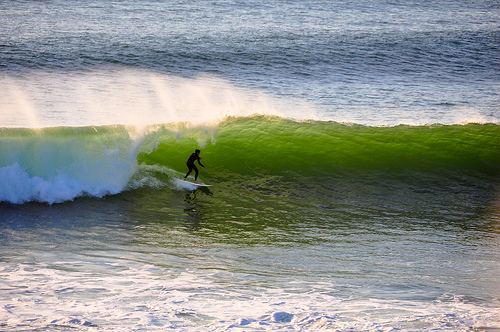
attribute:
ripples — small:
[18, 284, 78, 316]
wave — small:
[329, 26, 399, 116]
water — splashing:
[261, 12, 450, 108]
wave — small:
[1, 110, 494, 214]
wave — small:
[387, 301, 442, 326]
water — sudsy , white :
[337, 136, 437, 273]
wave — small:
[46, 55, 188, 225]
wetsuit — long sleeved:
[168, 148, 213, 189]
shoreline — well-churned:
[6, 311, 491, 330]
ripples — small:
[12, 262, 497, 329]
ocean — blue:
[6, 8, 498, 114]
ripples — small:
[93, 291, 313, 329]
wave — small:
[0, 27, 499, 80]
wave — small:
[0, 116, 481, 202]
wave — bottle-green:
[126, 119, 479, 206]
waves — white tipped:
[0, 217, 482, 329]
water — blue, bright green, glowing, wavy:
[4, 3, 484, 330]